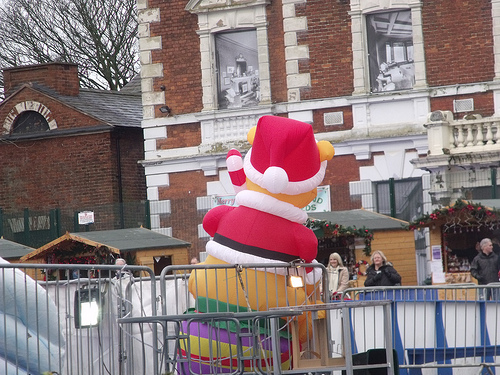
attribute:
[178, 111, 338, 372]
decoration — Christmas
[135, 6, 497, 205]
brickbuilding — brick, light red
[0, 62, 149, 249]
building — old, brick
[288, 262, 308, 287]
outdoor light — hanging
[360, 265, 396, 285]
jacket — black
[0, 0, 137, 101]
tree — large, leafless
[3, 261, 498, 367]
fence — silver, metal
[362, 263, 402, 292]
jacket — black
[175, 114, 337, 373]
display — inflatable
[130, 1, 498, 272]
building — old, brick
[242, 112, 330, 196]
hat — red